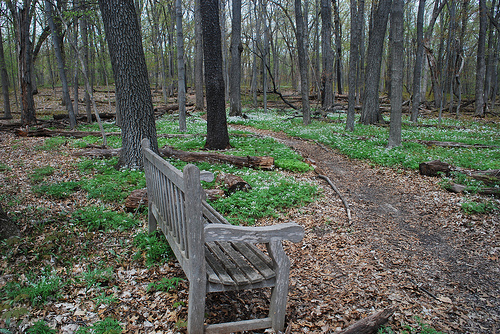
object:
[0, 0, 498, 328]
forrest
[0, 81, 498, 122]
fence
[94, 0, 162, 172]
tree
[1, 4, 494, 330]
park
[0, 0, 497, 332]
forest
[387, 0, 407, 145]
tree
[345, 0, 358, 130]
tree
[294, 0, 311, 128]
tree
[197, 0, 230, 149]
tree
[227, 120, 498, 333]
trail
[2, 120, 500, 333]
dirt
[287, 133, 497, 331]
leaves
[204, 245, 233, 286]
slat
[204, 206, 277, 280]
wooden slat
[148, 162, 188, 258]
wooden slat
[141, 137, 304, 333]
bench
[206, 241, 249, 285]
slat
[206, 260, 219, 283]
slat